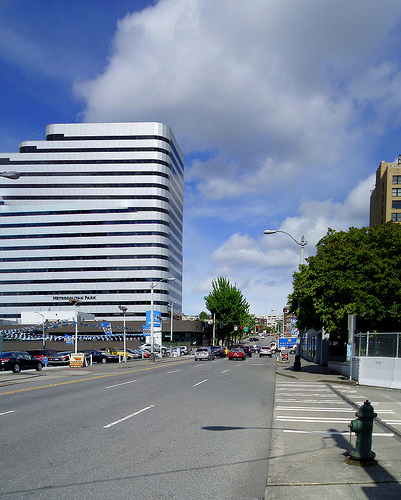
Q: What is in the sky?
A: Clouds.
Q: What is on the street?
A: Cars.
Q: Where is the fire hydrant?
A: To the right of the street.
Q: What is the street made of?
A: Concrete.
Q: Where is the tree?
A: On the right side.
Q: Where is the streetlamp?
A: On the right side.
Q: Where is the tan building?
A: Behind the tree.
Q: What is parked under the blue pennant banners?
A: Cars.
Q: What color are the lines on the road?
A: White.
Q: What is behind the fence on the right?
A: A tree.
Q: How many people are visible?
A: None.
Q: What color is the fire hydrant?
A: Green.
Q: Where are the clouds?
A: In the sky.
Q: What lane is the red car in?
A: The middle.